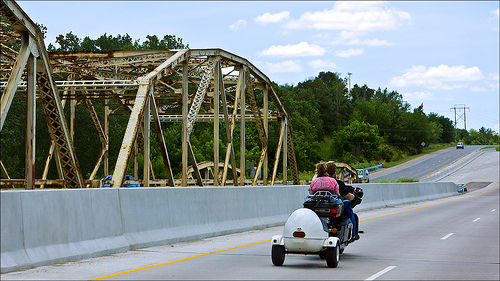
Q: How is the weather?
A: Fair.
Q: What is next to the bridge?
A: Guardrail.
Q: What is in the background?
A: Trees.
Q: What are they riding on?
A: Motorcycle.